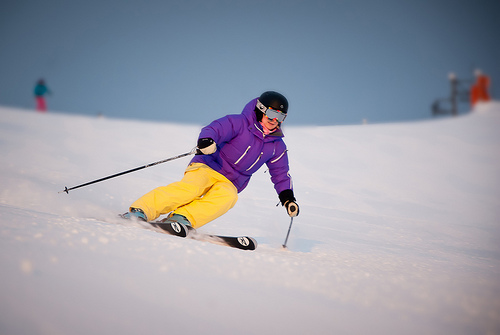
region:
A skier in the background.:
[15, 60, 75, 115]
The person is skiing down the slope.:
[55, 40, 317, 260]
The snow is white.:
[337, 175, 462, 297]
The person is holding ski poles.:
[90, 56, 312, 263]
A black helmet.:
[240, 85, 295, 140]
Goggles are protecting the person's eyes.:
[257, 102, 287, 122]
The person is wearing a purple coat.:
[195, 90, 300, 210]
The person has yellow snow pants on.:
[116, 137, 246, 237]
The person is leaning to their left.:
[106, 62, 311, 258]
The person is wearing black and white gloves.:
[167, 77, 304, 222]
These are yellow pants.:
[122, 145, 248, 241]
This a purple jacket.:
[190, 80, 330, 187]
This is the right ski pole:
[52, 130, 227, 200]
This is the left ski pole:
[272, 191, 307, 266]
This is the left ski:
[187, 202, 267, 260]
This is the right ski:
[116, 201, 202, 249]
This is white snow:
[324, 175, 389, 217]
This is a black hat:
[249, 79, 299, 144]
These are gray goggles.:
[247, 90, 294, 124]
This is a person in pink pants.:
[30, 60, 62, 119]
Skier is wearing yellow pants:
[123, 134, 222, 229]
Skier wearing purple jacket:
[176, 89, 282, 189]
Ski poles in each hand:
[69, 147, 327, 241]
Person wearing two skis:
[108, 201, 262, 266]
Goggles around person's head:
[243, 87, 302, 137]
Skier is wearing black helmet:
[247, 96, 299, 122]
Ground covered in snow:
[78, 230, 405, 304]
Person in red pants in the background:
[16, 85, 87, 127]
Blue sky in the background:
[131, 90, 371, 112]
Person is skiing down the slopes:
[156, 87, 323, 282]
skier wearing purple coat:
[114, 89, 309, 235]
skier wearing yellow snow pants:
[120, 91, 309, 243]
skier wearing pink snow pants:
[31, 77, 58, 112]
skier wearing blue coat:
[32, 79, 54, 109]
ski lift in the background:
[431, 69, 492, 121]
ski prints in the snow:
[6, 201, 498, 280]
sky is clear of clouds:
[1, 0, 497, 131]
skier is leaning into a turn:
[111, 91, 330, 233]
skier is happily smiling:
[113, 89, 328, 251]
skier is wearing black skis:
[91, 89, 306, 251]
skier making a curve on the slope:
[55, 37, 351, 272]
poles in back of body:
[60, 126, 310, 272]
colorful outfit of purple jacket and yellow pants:
[112, 70, 297, 260]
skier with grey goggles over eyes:
[240, 65, 300, 160]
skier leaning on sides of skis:
[106, 186, 266, 266]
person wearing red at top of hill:
[22, 60, 59, 131]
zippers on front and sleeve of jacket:
[175, 125, 300, 190]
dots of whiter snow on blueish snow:
[20, 200, 336, 311]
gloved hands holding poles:
[185, 125, 306, 240]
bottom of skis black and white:
[141, 213, 266, 254]